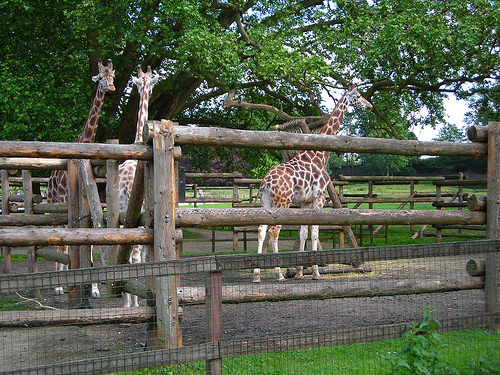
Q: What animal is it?
A: Giraffe.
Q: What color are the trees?
A: Green.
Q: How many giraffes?
A: Three.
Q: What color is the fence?
A: Brown.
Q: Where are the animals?
A: Behind fence.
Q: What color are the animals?
A: Brown and yellow.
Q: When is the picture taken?
A: Daytime.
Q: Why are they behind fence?
A: To keep enclosed.